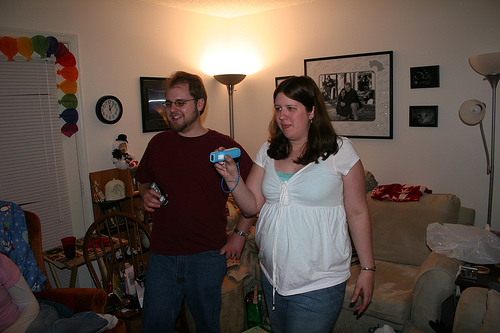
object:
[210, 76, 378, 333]
woman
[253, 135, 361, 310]
shirt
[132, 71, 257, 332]
man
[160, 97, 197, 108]
glasses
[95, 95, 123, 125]
clock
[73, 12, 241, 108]
wall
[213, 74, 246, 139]
lamp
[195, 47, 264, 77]
light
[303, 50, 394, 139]
picture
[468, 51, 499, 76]
lamp shade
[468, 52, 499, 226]
lamp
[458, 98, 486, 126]
lamp shade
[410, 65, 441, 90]
picture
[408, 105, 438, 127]
picture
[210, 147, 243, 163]
remote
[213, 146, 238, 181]
hand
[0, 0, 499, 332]
living room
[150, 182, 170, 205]
remote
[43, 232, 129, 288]
folding table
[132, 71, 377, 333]
man and woman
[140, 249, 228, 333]
jeans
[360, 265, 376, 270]
wrist watch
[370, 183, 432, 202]
blanket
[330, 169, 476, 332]
couch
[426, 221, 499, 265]
plastic bag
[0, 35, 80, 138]
decorative cut out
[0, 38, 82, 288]
window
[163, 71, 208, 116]
hair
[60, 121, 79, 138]
balloons